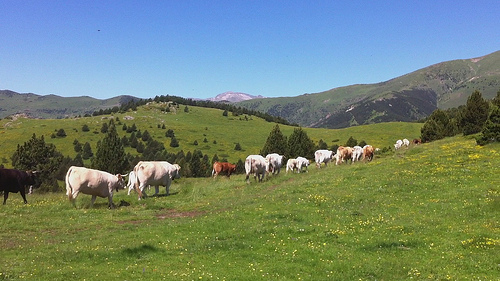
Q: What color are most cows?
A: White.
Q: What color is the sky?
A: Blue.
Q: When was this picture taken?
A: Daytime.